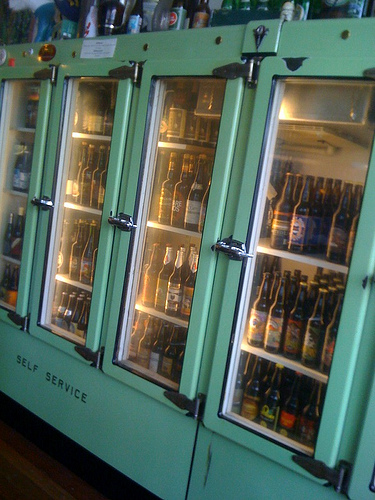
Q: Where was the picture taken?
A: Inside a store.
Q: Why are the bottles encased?
A: To stay cold.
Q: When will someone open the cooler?
A: When they get thirsty.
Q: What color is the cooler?
A: The cooler is green.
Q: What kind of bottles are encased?
A: Beer bottles.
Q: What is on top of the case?
A: There are bottles on top of the case.